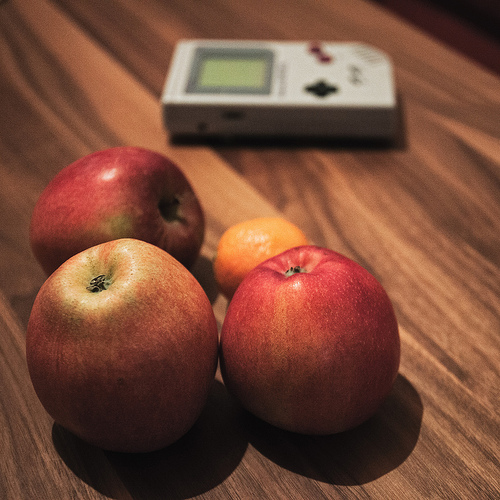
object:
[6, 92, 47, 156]
grain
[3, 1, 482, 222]
table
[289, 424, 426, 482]
shadow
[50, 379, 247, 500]
shadow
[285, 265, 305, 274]
stem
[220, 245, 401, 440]
apple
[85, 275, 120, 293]
stem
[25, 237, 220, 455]
apple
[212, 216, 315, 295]
orange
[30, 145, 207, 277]
apple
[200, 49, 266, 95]
square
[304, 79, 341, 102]
cross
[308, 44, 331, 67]
dot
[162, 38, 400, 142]
device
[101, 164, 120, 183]
light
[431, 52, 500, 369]
wood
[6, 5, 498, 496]
room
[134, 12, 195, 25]
up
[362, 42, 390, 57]
corner